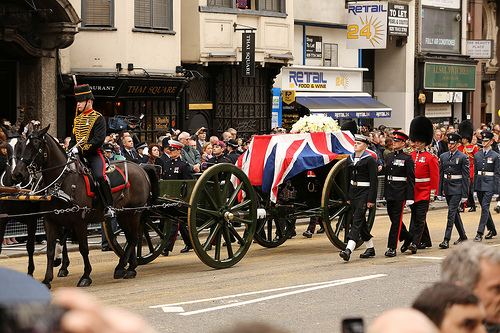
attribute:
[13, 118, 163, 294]
horse — brown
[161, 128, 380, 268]
wagon — green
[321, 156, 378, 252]
wheel — spoked, green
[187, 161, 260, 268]
wheel — spoked, green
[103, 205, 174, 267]
wheel — spoked, green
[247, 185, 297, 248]
wheel — spoked, green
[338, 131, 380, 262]
man — walking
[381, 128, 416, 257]
man — walking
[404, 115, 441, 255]
man — walking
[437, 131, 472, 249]
man — walking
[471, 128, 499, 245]
man — walking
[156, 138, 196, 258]
man — walking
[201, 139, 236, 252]
man — walking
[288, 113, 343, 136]
flowers — white